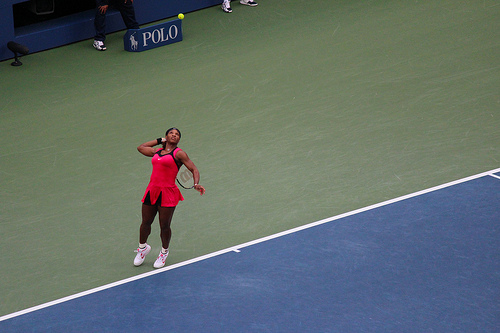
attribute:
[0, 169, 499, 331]
court — blue